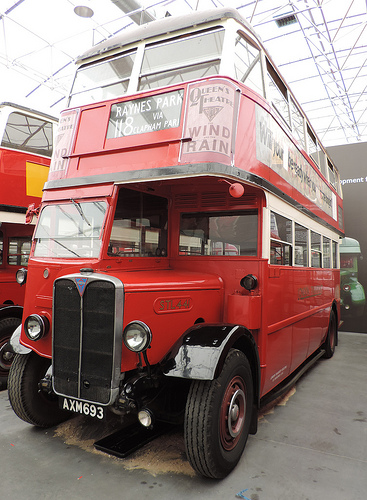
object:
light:
[138, 411, 151, 427]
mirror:
[228, 182, 244, 198]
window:
[268, 208, 293, 265]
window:
[323, 236, 331, 268]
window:
[30, 196, 109, 259]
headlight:
[23, 313, 50, 341]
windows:
[268, 209, 338, 269]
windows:
[234, 29, 342, 198]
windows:
[67, 24, 225, 109]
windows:
[33, 200, 110, 258]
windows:
[178, 208, 259, 256]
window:
[294, 222, 309, 268]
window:
[310, 229, 322, 268]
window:
[322, 236, 331, 269]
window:
[332, 240, 336, 269]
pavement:
[0, 332, 367, 498]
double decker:
[30, 7, 346, 272]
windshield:
[178, 207, 259, 256]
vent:
[51, 269, 124, 406]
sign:
[106, 88, 185, 139]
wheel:
[185, 349, 254, 482]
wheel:
[6, 352, 57, 428]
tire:
[322, 309, 337, 358]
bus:
[7, 6, 344, 481]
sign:
[178, 78, 242, 167]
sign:
[47, 108, 79, 182]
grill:
[51, 272, 125, 407]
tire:
[183, 348, 254, 484]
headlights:
[23, 313, 153, 353]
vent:
[274, 14, 300, 29]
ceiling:
[0, 0, 367, 151]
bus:
[0, 99, 63, 393]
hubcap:
[228, 388, 247, 438]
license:
[60, 396, 104, 423]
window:
[321, 234, 338, 268]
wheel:
[182, 343, 272, 482]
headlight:
[121, 320, 152, 353]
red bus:
[6, 7, 344, 482]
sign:
[46, 78, 241, 182]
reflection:
[33, 201, 107, 259]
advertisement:
[254, 102, 337, 223]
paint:
[26, 161, 50, 197]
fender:
[163, 325, 240, 380]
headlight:
[23, 310, 45, 347]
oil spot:
[140, 480, 164, 488]